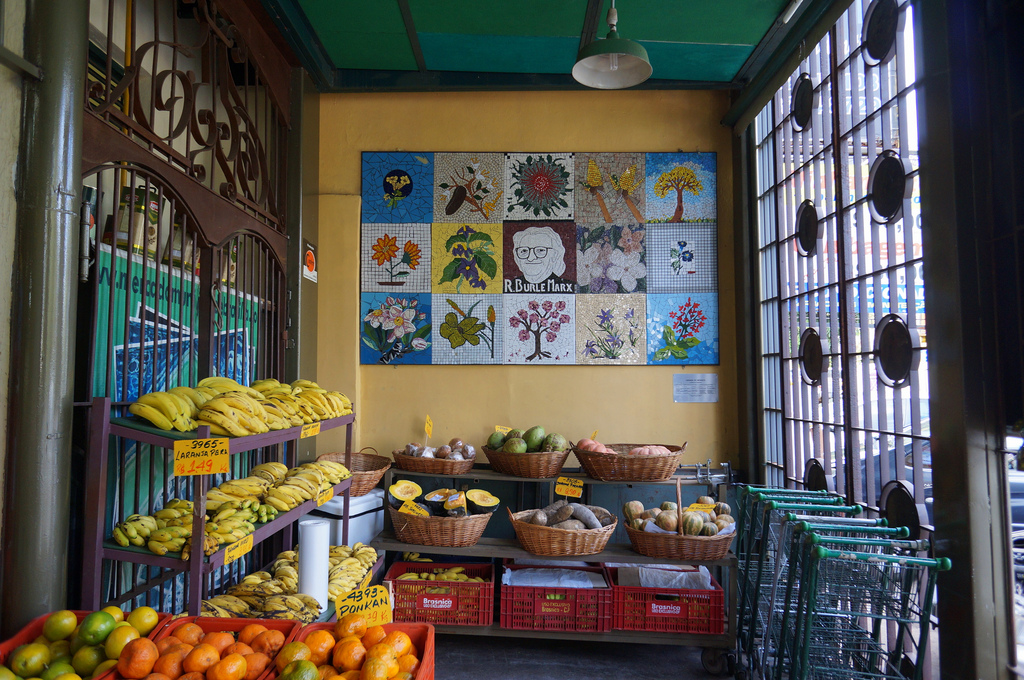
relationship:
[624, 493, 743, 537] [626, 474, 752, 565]
fruit in basket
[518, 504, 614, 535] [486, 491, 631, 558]
fruit in basket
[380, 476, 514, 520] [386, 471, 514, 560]
fruit in basket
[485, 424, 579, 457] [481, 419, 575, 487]
fruit in basket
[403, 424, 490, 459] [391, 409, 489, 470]
fruit in basket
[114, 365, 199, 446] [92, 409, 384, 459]
bananas on shelf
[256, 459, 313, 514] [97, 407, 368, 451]
bananas on shelf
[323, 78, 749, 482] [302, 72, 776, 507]
artwork hanging on yellow wall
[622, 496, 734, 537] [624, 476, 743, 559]
fruit in basket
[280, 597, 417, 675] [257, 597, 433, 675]
orange fruit in basket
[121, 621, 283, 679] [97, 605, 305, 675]
fruits in basket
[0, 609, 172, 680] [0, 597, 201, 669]
basket in basket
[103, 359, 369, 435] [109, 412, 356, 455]
yellow bananas stacked on shelf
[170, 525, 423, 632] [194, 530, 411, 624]
yellow bananas on bottom bottom shelf